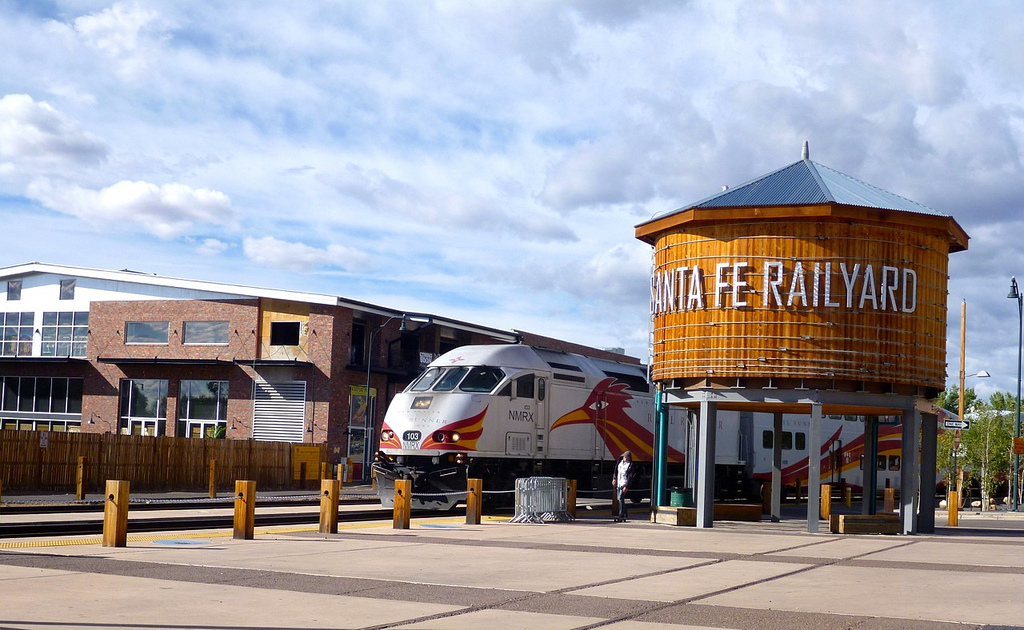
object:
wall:
[307, 301, 400, 473]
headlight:
[429, 426, 464, 445]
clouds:
[0, 3, 1016, 384]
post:
[99, 476, 131, 545]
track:
[2, 487, 470, 542]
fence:
[0, 430, 336, 493]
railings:
[5, 457, 328, 498]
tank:
[633, 141, 970, 390]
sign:
[942, 418, 970, 429]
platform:
[0, 512, 1019, 627]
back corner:
[821, 201, 971, 251]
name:
[647, 259, 920, 309]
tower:
[636, 131, 965, 531]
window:
[126, 320, 169, 343]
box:
[515, 473, 575, 521]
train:
[380, 337, 1015, 495]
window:
[406, 361, 502, 393]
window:
[184, 320, 230, 343]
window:
[118, 320, 239, 347]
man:
[603, 450, 638, 521]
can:
[652, 447, 709, 526]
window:
[0, 310, 88, 357]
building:
[0, 261, 356, 492]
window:
[270, 322, 300, 346]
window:
[120, 379, 228, 419]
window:
[47, 375, 83, 414]